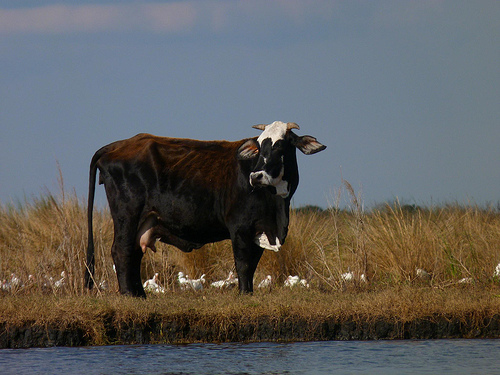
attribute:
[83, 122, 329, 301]
cow — brown, black, white, female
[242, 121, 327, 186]
head — black, white, turned right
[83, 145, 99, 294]
tail — long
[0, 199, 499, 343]
grass — brown, tall, dry, dead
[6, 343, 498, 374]
water — blue, calm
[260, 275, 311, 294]
trash — white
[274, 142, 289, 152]
eye — black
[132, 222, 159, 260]
utters — pink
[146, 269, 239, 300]
birds — white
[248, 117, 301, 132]
horns — small, grey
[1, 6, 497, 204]
sky — grey, clear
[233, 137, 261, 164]
ear — pink, brown